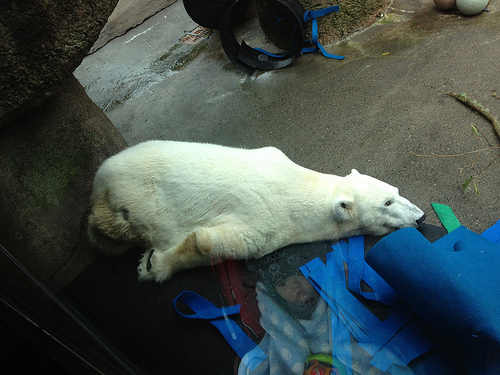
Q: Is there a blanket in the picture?
A: Yes, there is a blanket.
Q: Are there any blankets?
A: Yes, there is a blanket.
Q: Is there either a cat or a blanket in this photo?
A: Yes, there is a blanket.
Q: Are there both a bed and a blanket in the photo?
A: No, there is a blanket but no beds.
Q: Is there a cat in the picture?
A: No, there are no cats.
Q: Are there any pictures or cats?
A: No, there are no cats or pictures.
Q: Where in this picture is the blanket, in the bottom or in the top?
A: The blanket is in the bottom of the image.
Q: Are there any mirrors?
A: No, there are no mirrors.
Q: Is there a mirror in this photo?
A: No, there are no mirrors.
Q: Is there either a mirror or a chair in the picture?
A: No, there are no mirrors or chairs.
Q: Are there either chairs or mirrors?
A: No, there are no mirrors or chairs.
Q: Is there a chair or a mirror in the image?
A: No, there are no mirrors or chairs.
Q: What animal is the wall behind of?
A: The wall is behind the bear.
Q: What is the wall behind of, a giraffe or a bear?
A: The wall is behind a bear.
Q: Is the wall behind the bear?
A: Yes, the wall is behind the bear.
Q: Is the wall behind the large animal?
A: Yes, the wall is behind the bear.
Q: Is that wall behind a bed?
A: No, the wall is behind the bear.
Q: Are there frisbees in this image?
A: No, there are no frisbees.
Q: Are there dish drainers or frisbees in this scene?
A: No, there are no frisbees or dish drainers.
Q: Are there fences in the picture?
A: No, there are no fences.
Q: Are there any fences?
A: No, there are no fences.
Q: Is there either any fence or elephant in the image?
A: No, there are no fences or elephants.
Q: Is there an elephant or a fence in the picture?
A: No, there are no fences or elephants.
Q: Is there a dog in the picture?
A: No, there are no dogs.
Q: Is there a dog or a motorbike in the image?
A: No, there are no dogs or motorcycles.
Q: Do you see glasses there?
A: No, there are no glasses.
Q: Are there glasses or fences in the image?
A: No, there are no glasses or fences.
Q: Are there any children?
A: Yes, there is a child.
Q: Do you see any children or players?
A: Yes, there is a child.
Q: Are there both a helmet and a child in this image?
A: No, there is a child but no helmets.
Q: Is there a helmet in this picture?
A: No, there are no helmets.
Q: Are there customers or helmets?
A: No, there are no helmets or customers.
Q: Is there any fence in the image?
A: No, there are no fences.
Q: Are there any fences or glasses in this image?
A: No, there are no fences or glasses.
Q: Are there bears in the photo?
A: Yes, there is a bear.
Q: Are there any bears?
A: Yes, there is a bear.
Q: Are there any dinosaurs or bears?
A: Yes, there is a bear.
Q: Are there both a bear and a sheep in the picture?
A: No, there is a bear but no sheep.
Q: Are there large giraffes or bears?
A: Yes, there is a large bear.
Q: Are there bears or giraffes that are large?
A: Yes, the bear is large.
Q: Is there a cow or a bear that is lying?
A: Yes, the bear is lying.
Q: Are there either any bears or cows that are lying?
A: Yes, the bear is lying.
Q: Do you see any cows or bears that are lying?
A: Yes, the bear is lying.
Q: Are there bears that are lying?
A: Yes, there is a bear that is lying.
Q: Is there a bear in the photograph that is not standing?
A: Yes, there is a bear that is lying.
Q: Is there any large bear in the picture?
A: Yes, there is a large bear.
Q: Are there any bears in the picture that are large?
A: Yes, there is a bear that is large.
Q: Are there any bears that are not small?
A: Yes, there is a large bear.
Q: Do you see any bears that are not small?
A: Yes, there is a large bear.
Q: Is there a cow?
A: No, there are no cows.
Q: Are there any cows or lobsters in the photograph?
A: No, there are no cows or lobsters.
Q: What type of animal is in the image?
A: The animal is a bear.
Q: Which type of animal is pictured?
A: The animal is a bear.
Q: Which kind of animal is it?
A: The animal is a bear.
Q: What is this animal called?
A: This is a bear.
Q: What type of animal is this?
A: This is a bear.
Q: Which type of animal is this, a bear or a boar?
A: This is a bear.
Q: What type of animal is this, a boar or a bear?
A: This is a bear.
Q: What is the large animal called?
A: The animal is a bear.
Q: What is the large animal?
A: The animal is a bear.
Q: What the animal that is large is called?
A: The animal is a bear.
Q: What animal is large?
A: The animal is a bear.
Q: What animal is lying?
A: The animal is a bear.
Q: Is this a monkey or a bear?
A: This is a bear.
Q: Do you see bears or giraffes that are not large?
A: No, there is a bear but it is large.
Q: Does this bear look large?
A: Yes, the bear is large.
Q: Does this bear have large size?
A: Yes, the bear is large.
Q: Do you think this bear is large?
A: Yes, the bear is large.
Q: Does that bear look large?
A: Yes, the bear is large.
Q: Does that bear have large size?
A: Yes, the bear is large.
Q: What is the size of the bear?
A: The bear is large.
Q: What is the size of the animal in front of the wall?
A: The bear is large.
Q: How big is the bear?
A: The bear is large.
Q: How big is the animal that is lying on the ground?
A: The bear is large.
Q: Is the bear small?
A: No, the bear is large.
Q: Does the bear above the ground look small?
A: No, the bear is large.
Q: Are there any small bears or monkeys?
A: No, there is a bear but it is large.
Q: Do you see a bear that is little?
A: No, there is a bear but it is large.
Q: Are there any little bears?
A: No, there is a bear but it is large.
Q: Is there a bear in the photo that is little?
A: No, there is a bear but it is large.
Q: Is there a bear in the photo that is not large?
A: No, there is a bear but it is large.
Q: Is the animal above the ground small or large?
A: The bear is large.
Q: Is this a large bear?
A: Yes, this is a large bear.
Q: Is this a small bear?
A: No, this is a large bear.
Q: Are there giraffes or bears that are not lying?
A: No, there is a bear but it is lying.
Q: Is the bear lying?
A: Yes, the bear is lying.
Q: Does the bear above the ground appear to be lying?
A: Yes, the bear is lying.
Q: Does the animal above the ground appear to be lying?
A: Yes, the bear is lying.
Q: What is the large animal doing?
A: The bear is lying.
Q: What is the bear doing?
A: The bear is lying.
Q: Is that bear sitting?
A: No, the bear is lying.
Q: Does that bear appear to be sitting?
A: No, the bear is lying.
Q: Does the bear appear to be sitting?
A: No, the bear is lying.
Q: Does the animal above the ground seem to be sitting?
A: No, the bear is lying.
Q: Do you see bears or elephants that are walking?
A: No, there is a bear but it is lying.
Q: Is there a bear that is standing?
A: No, there is a bear but it is lying.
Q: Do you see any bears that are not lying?
A: No, there is a bear but it is lying.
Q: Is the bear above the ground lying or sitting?
A: The bear is lying.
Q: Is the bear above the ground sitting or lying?
A: The bear is lying.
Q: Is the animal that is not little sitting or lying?
A: The bear is lying.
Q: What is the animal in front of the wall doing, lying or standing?
A: The bear is lying.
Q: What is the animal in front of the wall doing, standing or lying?
A: The bear is lying.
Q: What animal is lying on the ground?
A: The animal is a bear.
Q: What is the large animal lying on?
A: The bear is lying on the ground.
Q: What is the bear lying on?
A: The bear is lying on the ground.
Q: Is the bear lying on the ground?
A: Yes, the bear is lying on the ground.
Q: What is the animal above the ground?
A: The animal is a bear.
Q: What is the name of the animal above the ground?
A: The animal is a bear.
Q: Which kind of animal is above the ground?
A: The animal is a bear.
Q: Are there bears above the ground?
A: Yes, there is a bear above the ground.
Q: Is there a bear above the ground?
A: Yes, there is a bear above the ground.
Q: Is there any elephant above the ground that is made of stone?
A: No, there is a bear above the ground.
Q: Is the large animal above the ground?
A: Yes, the bear is above the ground.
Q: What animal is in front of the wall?
A: The bear is in front of the wall.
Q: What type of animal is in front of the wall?
A: The animal is a bear.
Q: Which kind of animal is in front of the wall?
A: The animal is a bear.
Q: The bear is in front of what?
A: The bear is in front of the wall.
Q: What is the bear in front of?
A: The bear is in front of the wall.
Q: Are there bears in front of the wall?
A: Yes, there is a bear in front of the wall.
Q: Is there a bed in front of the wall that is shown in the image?
A: No, there is a bear in front of the wall.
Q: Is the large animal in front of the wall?
A: Yes, the bear is in front of the wall.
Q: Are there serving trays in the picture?
A: No, there are no serving trays.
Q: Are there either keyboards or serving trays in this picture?
A: No, there are no serving trays or keyboards.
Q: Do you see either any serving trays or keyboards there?
A: No, there are no serving trays or keyboards.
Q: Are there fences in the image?
A: No, there are no fences.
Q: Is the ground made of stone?
A: Yes, the ground is made of stone.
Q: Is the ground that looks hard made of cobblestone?
A: No, the ground is made of stone.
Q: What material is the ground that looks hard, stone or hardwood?
A: The ground is made of stone.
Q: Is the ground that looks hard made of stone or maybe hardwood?
A: The ground is made of stone.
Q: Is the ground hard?
A: Yes, the ground is hard.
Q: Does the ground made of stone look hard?
A: Yes, the ground is hard.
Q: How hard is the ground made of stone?
A: The ground is hard.